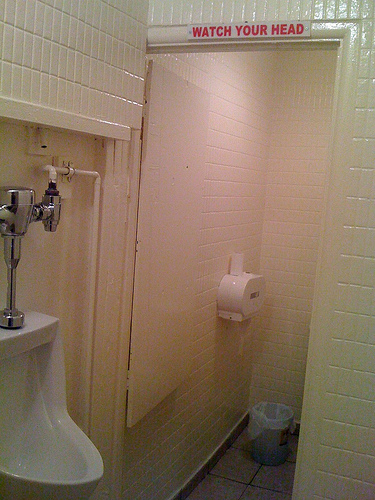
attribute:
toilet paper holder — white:
[212, 243, 267, 337]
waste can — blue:
[245, 404, 301, 473]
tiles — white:
[305, 327, 374, 499]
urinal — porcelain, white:
[0, 303, 113, 496]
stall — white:
[116, 46, 371, 490]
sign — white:
[168, 19, 317, 47]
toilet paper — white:
[212, 253, 272, 327]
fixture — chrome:
[3, 187, 80, 332]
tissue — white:
[226, 319, 271, 380]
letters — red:
[183, 24, 306, 39]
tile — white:
[312, 360, 367, 449]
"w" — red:
[185, 23, 203, 44]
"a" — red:
[199, 27, 211, 44]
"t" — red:
[204, 22, 221, 43]